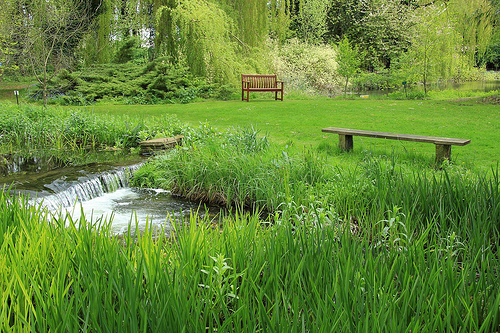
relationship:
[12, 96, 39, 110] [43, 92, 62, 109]
pole in ground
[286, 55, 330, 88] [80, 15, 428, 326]
bush in park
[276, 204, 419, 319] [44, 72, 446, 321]
grass in park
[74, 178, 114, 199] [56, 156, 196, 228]
waterfall in pond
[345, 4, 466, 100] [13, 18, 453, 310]
bush in park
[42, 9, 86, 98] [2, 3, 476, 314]
tree in park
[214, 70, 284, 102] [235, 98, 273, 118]
bench sitting on grass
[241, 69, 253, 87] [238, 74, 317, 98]
arm on bench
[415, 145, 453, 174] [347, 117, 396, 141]
blocks support board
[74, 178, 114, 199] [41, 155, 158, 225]
waterfall on a creek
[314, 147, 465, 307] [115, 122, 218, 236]
weeds surround creek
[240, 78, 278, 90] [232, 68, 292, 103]
back on bench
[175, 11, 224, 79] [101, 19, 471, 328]
willows at back property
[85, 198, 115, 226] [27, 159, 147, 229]
foam from waterfall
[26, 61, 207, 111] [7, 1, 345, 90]
shrubs beneath trees